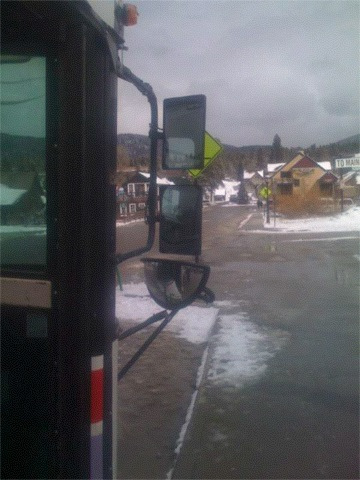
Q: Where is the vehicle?
A: On the slush.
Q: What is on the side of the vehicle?
A: Mirrors.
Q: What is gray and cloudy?
A: The sky.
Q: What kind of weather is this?
A: Snowy.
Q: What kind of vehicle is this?
A: A bus.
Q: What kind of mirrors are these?
A: Mirrors for the bus.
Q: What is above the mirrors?
A: A small orange light.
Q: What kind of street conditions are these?
A: Winter driving conditions.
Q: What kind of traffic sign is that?
A: A yellow pedestrian sign.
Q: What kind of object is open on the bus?
A: The door.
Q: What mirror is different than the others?
A: The small round mirror.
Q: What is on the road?
A: Snow.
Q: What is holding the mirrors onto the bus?
A: Sturdy metal rods.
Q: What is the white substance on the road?
A: Snow and ice.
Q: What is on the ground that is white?
A: Snow.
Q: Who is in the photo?
A: No one.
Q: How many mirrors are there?
A: 3.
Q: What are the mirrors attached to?
A: Bus.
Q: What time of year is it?
A: Winter.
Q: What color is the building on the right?
A: Tan.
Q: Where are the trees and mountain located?
A: Background.